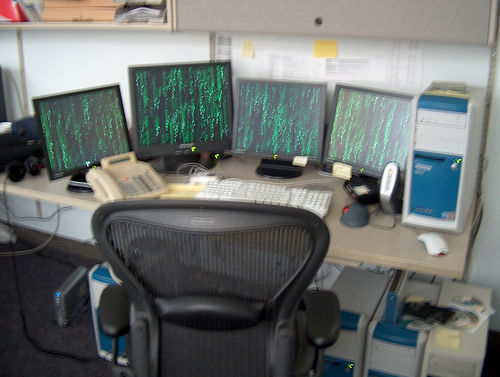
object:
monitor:
[132, 65, 230, 148]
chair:
[90, 194, 340, 376]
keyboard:
[195, 178, 332, 220]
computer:
[128, 62, 231, 173]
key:
[306, 183, 334, 191]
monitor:
[328, 86, 411, 172]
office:
[0, 0, 500, 377]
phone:
[84, 150, 168, 202]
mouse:
[341, 204, 370, 226]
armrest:
[97, 280, 132, 336]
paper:
[313, 36, 336, 58]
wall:
[15, 30, 128, 83]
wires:
[0, 200, 90, 255]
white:
[215, 36, 232, 61]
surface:
[160, 159, 456, 260]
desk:
[0, 148, 474, 279]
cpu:
[402, 80, 479, 236]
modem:
[344, 177, 380, 206]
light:
[380, 161, 402, 215]